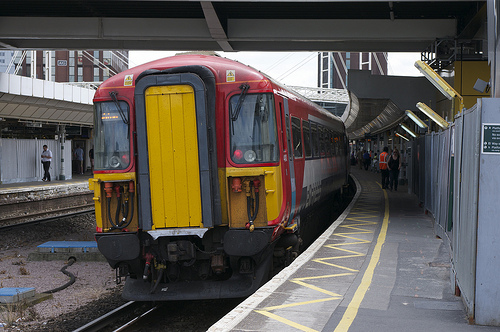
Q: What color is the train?
A: Red.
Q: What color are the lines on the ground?
A: Yellow.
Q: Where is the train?
A: Tracks.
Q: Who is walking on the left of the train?
A: Man.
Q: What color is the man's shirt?
A: White.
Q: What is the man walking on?
A: Sidewalk.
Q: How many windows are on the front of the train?
A: Two.